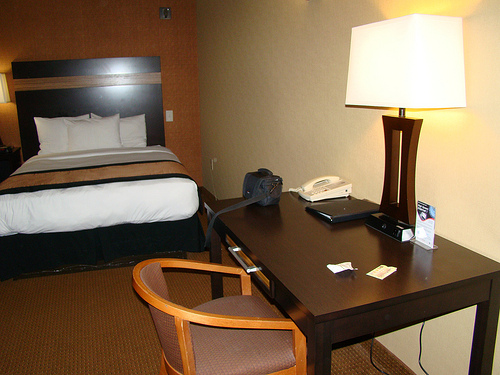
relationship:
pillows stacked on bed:
[22, 105, 224, 185] [21, 122, 226, 237]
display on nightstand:
[296, 14, 466, 282] [204, 191, 500, 374]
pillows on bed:
[33, 112, 147, 155] [1, 53, 208, 280]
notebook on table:
[374, 263, 392, 277] [207, 213, 450, 311]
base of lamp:
[372, 107, 427, 227] [337, 9, 469, 247]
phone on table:
[288, 173, 354, 202] [206, 178, 498, 374]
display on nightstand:
[344, 13, 467, 232] [201, 180, 499, 372]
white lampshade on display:
[343, 14, 466, 109] [344, 13, 467, 232]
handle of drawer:
[227, 244, 260, 276] [220, 231, 276, 305]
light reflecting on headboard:
[104, 66, 134, 100] [61, 51, 152, 111]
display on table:
[344, 13, 467, 232] [201, 166, 459, 316]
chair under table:
[126, 252, 315, 374] [206, 178, 498, 374]